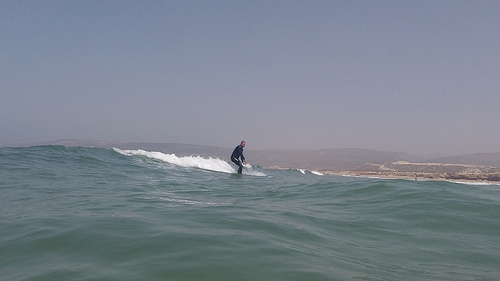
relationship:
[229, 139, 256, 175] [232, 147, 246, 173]
man in wetsuit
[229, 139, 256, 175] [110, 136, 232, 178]
man surfing waves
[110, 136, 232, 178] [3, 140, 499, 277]
waves in ocean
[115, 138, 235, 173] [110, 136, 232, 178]
whitecap on waves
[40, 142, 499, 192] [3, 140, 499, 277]
shoreline at ocean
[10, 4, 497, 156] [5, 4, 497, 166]
sky with haze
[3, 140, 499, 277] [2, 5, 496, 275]
ocean on day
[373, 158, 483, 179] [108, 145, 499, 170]
paths into mountains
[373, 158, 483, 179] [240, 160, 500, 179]
paths along coast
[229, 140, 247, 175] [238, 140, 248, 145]
man with hair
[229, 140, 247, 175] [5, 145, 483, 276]
man in water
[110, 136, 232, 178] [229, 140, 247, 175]
waves behind man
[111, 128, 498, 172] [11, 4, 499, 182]
moutains in distance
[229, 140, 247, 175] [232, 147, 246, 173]
man wearing wetsuit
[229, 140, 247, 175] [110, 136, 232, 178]
man riding waves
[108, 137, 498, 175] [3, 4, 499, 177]
land in background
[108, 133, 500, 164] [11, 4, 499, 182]
tops in distance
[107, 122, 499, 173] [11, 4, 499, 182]
hills in distance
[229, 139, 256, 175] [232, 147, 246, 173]
man wearing wetsuit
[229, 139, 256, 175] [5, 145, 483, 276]
man on water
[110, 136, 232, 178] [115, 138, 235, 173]
waves has whitecap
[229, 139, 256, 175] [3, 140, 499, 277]
man in ocean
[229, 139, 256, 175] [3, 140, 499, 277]
man surfing in ocean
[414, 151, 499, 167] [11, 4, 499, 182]
mountains in distance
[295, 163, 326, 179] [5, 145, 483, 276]
splash on water